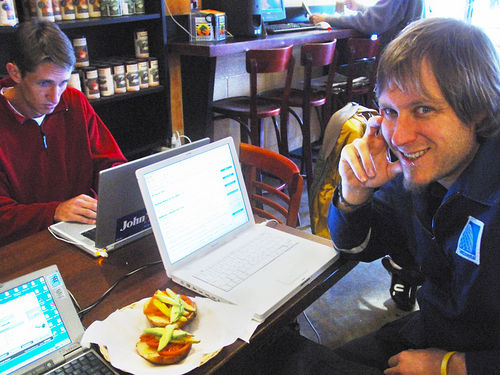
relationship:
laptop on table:
[134, 135, 344, 322] [2, 212, 362, 374]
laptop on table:
[0, 263, 120, 374] [2, 212, 362, 374]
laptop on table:
[48, 136, 210, 259] [2, 212, 362, 374]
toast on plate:
[134, 326, 196, 368] [98, 295, 228, 374]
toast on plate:
[140, 288, 200, 326] [98, 295, 228, 374]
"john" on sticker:
[120, 214, 148, 234] [116, 210, 151, 239]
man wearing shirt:
[1, 18, 131, 241] [0, 78, 123, 243]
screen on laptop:
[144, 144, 249, 265] [134, 135, 344, 322]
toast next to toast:
[134, 326, 196, 368] [140, 288, 200, 326]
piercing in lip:
[410, 159, 415, 167] [397, 153, 430, 165]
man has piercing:
[327, 17, 498, 373] [410, 159, 415, 167]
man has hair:
[327, 17, 498, 373] [375, 17, 500, 142]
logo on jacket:
[454, 216, 484, 266] [329, 137, 500, 374]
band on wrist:
[438, 350, 460, 373] [433, 350, 466, 374]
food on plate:
[137, 288, 198, 366] [98, 295, 228, 374]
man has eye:
[327, 17, 498, 373] [416, 107, 434, 116]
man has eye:
[327, 17, 498, 373] [382, 108, 396, 119]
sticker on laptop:
[116, 210, 151, 239] [48, 136, 210, 259]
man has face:
[327, 17, 498, 373] [376, 60, 475, 192]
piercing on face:
[410, 159, 415, 167] [376, 60, 475, 192]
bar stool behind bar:
[213, 44, 295, 158] [169, 23, 380, 157]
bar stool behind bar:
[261, 40, 340, 232] [169, 23, 380, 157]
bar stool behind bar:
[309, 37, 385, 129] [169, 23, 380, 157]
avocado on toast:
[155, 325, 181, 350] [134, 326, 196, 368]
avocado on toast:
[145, 325, 188, 338] [134, 326, 196, 368]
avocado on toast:
[169, 293, 183, 322] [140, 288, 200, 326]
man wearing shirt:
[327, 17, 498, 373] [0, 78, 123, 243]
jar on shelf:
[133, 29, 152, 59] [88, 87, 164, 104]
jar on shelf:
[74, 35, 92, 67] [88, 87, 164, 104]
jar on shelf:
[147, 57, 161, 86] [88, 87, 164, 104]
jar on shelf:
[136, 57, 150, 92] [88, 87, 164, 104]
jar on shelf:
[96, 65, 117, 97] [88, 87, 164, 104]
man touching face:
[327, 17, 498, 373] [376, 60, 475, 192]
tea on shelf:
[1, 0, 160, 28] [3, 14, 161, 34]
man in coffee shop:
[327, 17, 498, 373] [0, 1, 499, 374]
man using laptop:
[1, 18, 131, 241] [48, 136, 210, 259]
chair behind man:
[237, 141, 305, 230] [327, 17, 498, 373]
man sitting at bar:
[308, 0, 424, 45] [169, 23, 380, 157]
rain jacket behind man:
[313, 103, 372, 242] [327, 17, 498, 373]